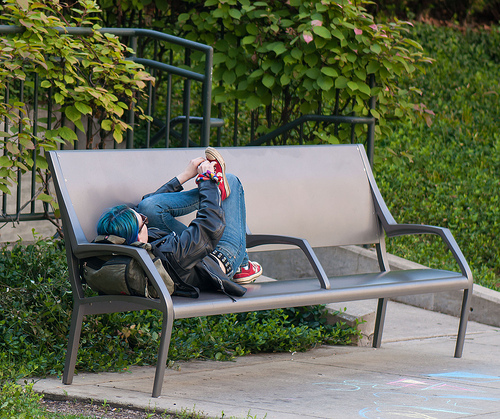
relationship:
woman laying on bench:
[100, 152, 262, 297] [46, 139, 473, 398]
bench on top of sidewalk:
[46, 139, 473, 398] [4, 241, 497, 419]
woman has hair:
[100, 152, 262, 297] [97, 204, 139, 246]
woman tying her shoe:
[100, 152, 262, 297] [201, 146, 230, 200]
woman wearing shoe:
[100, 152, 262, 297] [201, 146, 230, 200]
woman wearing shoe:
[100, 152, 262, 297] [234, 258, 262, 285]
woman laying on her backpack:
[100, 152, 262, 297] [81, 245, 175, 301]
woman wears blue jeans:
[100, 152, 262, 297] [200, 171, 253, 266]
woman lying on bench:
[100, 152, 262, 297] [46, 139, 473, 398]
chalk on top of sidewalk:
[393, 356, 490, 407] [4, 241, 497, 419]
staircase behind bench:
[1, 19, 379, 222] [46, 139, 473, 398]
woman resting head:
[100, 152, 262, 297] [100, 205, 152, 247]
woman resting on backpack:
[100, 152, 262, 297] [81, 245, 175, 301]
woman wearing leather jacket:
[100, 152, 262, 297] [112, 175, 224, 298]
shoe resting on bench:
[234, 258, 262, 285] [46, 139, 473, 398]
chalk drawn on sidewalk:
[393, 356, 490, 407] [4, 241, 497, 419]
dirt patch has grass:
[41, 388, 159, 418] [3, 380, 45, 419]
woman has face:
[100, 152, 262, 297] [129, 207, 153, 241]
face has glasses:
[129, 207, 153, 241] [133, 211, 151, 234]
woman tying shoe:
[100, 152, 262, 297] [201, 146, 230, 200]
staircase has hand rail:
[1, 19, 379, 222] [246, 107, 373, 146]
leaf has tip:
[302, 30, 315, 43] [305, 36, 312, 43]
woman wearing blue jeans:
[100, 152, 262, 297] [200, 171, 253, 266]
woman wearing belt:
[100, 152, 262, 297] [210, 247, 234, 276]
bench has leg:
[46, 139, 473, 398] [62, 294, 86, 386]